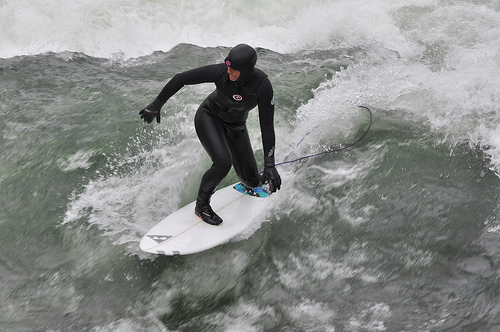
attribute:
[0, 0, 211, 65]
wave — crashing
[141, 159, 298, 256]
board — large, white, for surfing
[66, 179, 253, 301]
waves — white, gray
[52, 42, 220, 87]
waves — white, gray, ocean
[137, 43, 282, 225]
person — Surfing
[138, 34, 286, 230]
man — Surfing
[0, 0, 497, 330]
waves — gray, white, ocean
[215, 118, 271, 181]
leg — Surfing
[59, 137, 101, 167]
waves — white, gray, ocean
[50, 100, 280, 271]
ocean wave — white, gray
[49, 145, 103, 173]
ocean wave — white, gray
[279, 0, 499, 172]
ocean wave — white, gray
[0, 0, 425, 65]
ocean wave — white, gray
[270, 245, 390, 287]
ocean wave — white, gray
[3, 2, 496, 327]
ocean waves — white, gray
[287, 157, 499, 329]
waves — white, gray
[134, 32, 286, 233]
person — Surfing